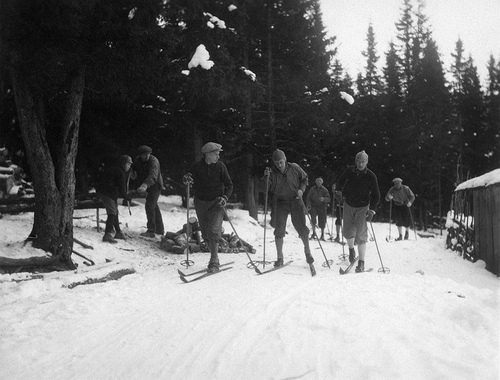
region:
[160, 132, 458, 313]
People skiing on snow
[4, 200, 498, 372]
Field is covered with snow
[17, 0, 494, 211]
Tall trees in background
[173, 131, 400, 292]
Tree men holding ski poles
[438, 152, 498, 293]
Cabin on right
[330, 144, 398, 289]
Man wearing black sweter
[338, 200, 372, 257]
Man wearing tan shorts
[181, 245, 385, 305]
Snowboards are narrow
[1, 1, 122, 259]
Big tree on path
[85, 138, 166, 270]
Two persons close to tree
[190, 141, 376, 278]
three people on skates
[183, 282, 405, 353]
the snow is white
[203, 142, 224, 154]
grey hat on mans head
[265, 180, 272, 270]
long ski pole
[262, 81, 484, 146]
trees in the background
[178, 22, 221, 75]
snow on tree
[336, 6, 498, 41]
it is a cloudy sky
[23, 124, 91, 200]
two tree trunks next to each other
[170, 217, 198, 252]
pile of wood next to the snow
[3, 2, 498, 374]
its daylight in the photo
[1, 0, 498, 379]
scene is monochrome [black+white]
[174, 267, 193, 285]
skis have curled tips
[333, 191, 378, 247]
man wears knickers, socks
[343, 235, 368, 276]
man wears knit knee socks, ski boots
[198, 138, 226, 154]
man wears slightly oversize newsboy/bakerboy cap, circa 1970s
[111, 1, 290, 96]
snow on tree appears floating on air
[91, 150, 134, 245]
tween age boy helps man throw wood onto fire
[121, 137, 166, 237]
only man in long pants helps boy throw wood onto fire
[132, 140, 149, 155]
man wears dark colored cap or tam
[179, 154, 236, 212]
man wears dark v-neck sweater over dark front-button shirt, which may be a henley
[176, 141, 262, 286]
a skier wearing a newsboy hat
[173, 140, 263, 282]
the skier has a pole in each hand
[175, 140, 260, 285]
the skier is wearing skis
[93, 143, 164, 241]
two men are sawing wood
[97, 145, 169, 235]
two men stand to the right of a tree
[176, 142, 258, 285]
the skier is looking to another man to his right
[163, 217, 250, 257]
there is a pile of logs behind the skier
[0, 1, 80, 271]
a large tree stands to the left of the skier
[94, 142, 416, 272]
all the men wear hats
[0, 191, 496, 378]
there is snow under the skiers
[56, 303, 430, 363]
Snow covered ground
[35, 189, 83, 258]
Thick tree trunk to the left of the skiiers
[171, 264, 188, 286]
Tips of the skis of the skiier on the left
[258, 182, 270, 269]
Pole in the right hand of the skiier in the middle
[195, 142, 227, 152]
Hat on the head of the skiier on the left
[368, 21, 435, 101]
Tall pine trees in the background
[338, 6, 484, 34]
Sky in the background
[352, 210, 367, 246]
Left leg of the skiier on the right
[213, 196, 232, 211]
Left hand of the skiier on the left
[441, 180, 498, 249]
Structure to the right of the skiiers